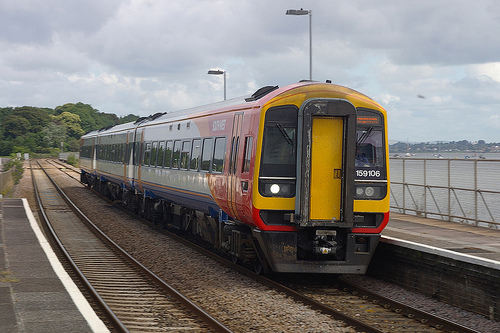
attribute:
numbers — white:
[355, 169, 382, 177]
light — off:
[283, 7, 308, 17]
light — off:
[205, 68, 225, 76]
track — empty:
[28, 156, 234, 331]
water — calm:
[386, 151, 498, 229]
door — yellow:
[308, 116, 343, 223]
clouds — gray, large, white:
[1, 2, 498, 144]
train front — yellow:
[252, 81, 392, 280]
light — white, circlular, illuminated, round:
[267, 182, 281, 196]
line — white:
[378, 233, 499, 267]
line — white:
[19, 197, 109, 332]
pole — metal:
[471, 156, 479, 225]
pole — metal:
[445, 156, 452, 218]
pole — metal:
[421, 156, 428, 214]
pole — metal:
[400, 155, 406, 213]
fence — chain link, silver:
[391, 158, 498, 230]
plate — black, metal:
[253, 231, 382, 275]